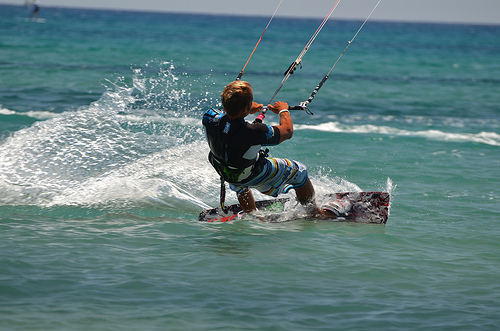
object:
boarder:
[200, 79, 317, 214]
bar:
[262, 106, 304, 111]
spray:
[0, 60, 208, 209]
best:
[208, 119, 247, 178]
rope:
[266, 80, 284, 106]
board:
[197, 192, 390, 225]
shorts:
[229, 156, 308, 197]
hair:
[221, 80, 253, 114]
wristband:
[279, 109, 289, 114]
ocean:
[3, 225, 500, 329]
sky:
[2, 2, 499, 28]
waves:
[480, 132, 500, 145]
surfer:
[28, 0, 42, 23]